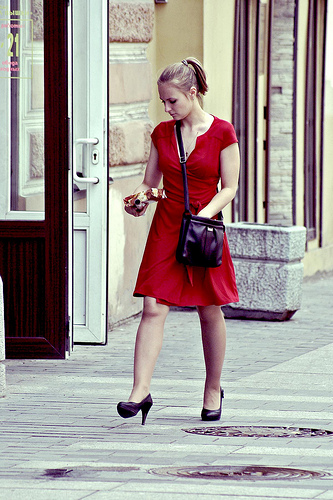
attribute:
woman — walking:
[116, 57, 239, 424]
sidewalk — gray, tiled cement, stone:
[1, 266, 331, 498]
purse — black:
[176, 117, 224, 268]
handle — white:
[74, 138, 100, 185]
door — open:
[3, 3, 106, 344]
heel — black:
[116, 394, 155, 426]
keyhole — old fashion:
[89, 147, 99, 166]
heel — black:
[200, 387, 225, 421]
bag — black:
[175, 120, 224, 267]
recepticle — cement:
[222, 223, 308, 323]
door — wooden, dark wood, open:
[3, 0, 69, 361]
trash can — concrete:
[220, 219, 305, 323]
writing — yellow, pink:
[10, 9, 47, 87]